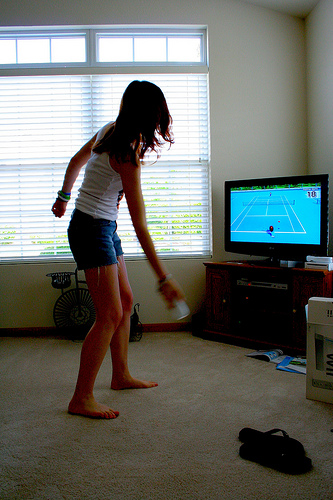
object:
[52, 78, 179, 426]
girl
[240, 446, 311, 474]
flip flops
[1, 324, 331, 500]
floor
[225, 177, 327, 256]
television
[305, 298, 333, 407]
box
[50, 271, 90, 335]
decoration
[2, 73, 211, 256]
blinds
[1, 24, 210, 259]
windows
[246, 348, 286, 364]
book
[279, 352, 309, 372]
papers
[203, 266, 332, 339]
console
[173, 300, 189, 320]
handle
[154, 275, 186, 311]
hand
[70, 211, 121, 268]
short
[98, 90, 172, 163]
hair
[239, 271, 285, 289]
dvd player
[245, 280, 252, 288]
light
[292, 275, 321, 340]
door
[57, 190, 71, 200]
bracelets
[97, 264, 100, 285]
fringe